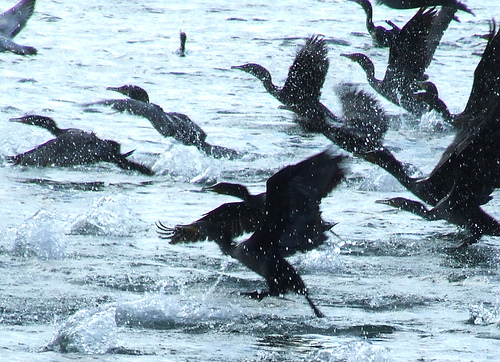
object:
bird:
[162, 144, 357, 245]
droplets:
[53, 189, 149, 239]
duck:
[282, 88, 421, 190]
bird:
[1, 115, 157, 173]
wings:
[337, 80, 388, 137]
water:
[0, 273, 253, 347]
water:
[15, 153, 212, 221]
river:
[13, 216, 156, 353]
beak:
[231, 64, 248, 71]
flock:
[0, 0, 498, 314]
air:
[48, 8, 172, 76]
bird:
[103, 85, 238, 161]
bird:
[346, 9, 458, 127]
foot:
[231, 280, 282, 300]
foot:
[444, 231, 480, 252]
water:
[55, 4, 177, 75]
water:
[328, 252, 495, 347]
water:
[13, 194, 240, 358]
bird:
[179, 30, 186, 58]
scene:
[1, 0, 498, 360]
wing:
[281, 34, 334, 105]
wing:
[158, 199, 244, 245]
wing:
[449, 99, 499, 205]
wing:
[460, 17, 498, 114]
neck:
[407, 191, 451, 221]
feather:
[305, 293, 325, 317]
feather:
[122, 160, 152, 177]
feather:
[198, 138, 235, 160]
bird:
[0, 0, 37, 57]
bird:
[8, 115, 153, 177]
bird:
[192, 226, 328, 318]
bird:
[187, 155, 327, 308]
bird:
[303, 82, 417, 188]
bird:
[373, 164, 498, 249]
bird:
[359, 92, 499, 208]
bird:
[235, 33, 351, 124]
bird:
[348, 2, 404, 46]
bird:
[373, 4, 463, 10]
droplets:
[415, 200, 425, 215]